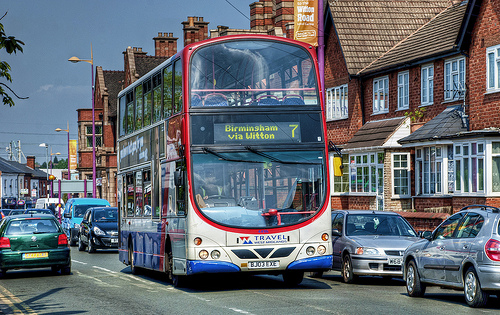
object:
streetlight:
[68, 56, 80, 63]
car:
[310, 209, 423, 284]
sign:
[293, 0, 324, 46]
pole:
[316, 0, 324, 108]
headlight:
[194, 237, 202, 246]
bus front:
[188, 34, 334, 272]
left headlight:
[321, 233, 329, 241]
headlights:
[199, 245, 326, 259]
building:
[326, 0, 500, 236]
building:
[68, 66, 121, 207]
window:
[415, 139, 500, 197]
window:
[444, 57, 465, 104]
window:
[371, 75, 389, 116]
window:
[87, 125, 103, 148]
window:
[485, 46, 500, 93]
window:
[142, 78, 152, 128]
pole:
[68, 42, 97, 197]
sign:
[225, 124, 299, 139]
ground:
[294, 117, 344, 168]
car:
[77, 205, 120, 253]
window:
[133, 84, 143, 131]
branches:
[0, 11, 31, 108]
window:
[119, 96, 126, 138]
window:
[188, 40, 321, 108]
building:
[0, 156, 85, 211]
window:
[162, 63, 173, 119]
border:
[181, 33, 331, 234]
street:
[0, 233, 498, 315]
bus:
[115, 34, 332, 288]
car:
[0, 213, 71, 277]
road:
[0, 242, 499, 315]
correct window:
[396, 70, 412, 110]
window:
[174, 57, 184, 114]